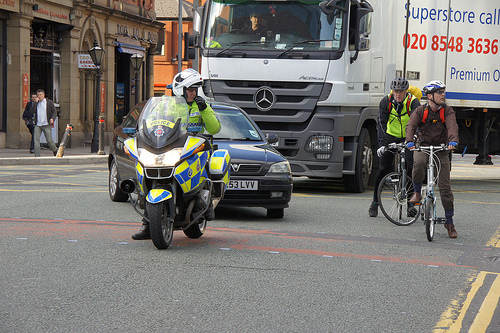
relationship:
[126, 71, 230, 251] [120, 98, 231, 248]
person on motorcycle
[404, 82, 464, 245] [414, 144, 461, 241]
men on bike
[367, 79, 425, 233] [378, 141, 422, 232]
person on bike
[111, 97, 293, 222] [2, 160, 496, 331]
car on street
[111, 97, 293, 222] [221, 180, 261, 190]
car has license plate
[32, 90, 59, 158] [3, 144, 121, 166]
person on sidewalk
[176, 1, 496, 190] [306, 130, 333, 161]
truck has headlight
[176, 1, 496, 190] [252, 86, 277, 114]
truck has emblem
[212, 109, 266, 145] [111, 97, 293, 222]
windshield on car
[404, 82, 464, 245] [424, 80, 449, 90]
men wearing helmet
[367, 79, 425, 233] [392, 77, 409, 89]
person wearing helmet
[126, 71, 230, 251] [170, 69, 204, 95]
person wearing a helmet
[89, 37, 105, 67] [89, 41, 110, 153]
light on a pole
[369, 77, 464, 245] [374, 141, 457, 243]
men on bikes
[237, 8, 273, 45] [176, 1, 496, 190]
man in truck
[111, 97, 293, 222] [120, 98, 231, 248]
car behind motorcycle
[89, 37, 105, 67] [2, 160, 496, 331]
light on street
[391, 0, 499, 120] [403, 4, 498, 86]
box has writing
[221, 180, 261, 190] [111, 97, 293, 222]
license plate on car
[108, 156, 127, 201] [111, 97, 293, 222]
tire on car